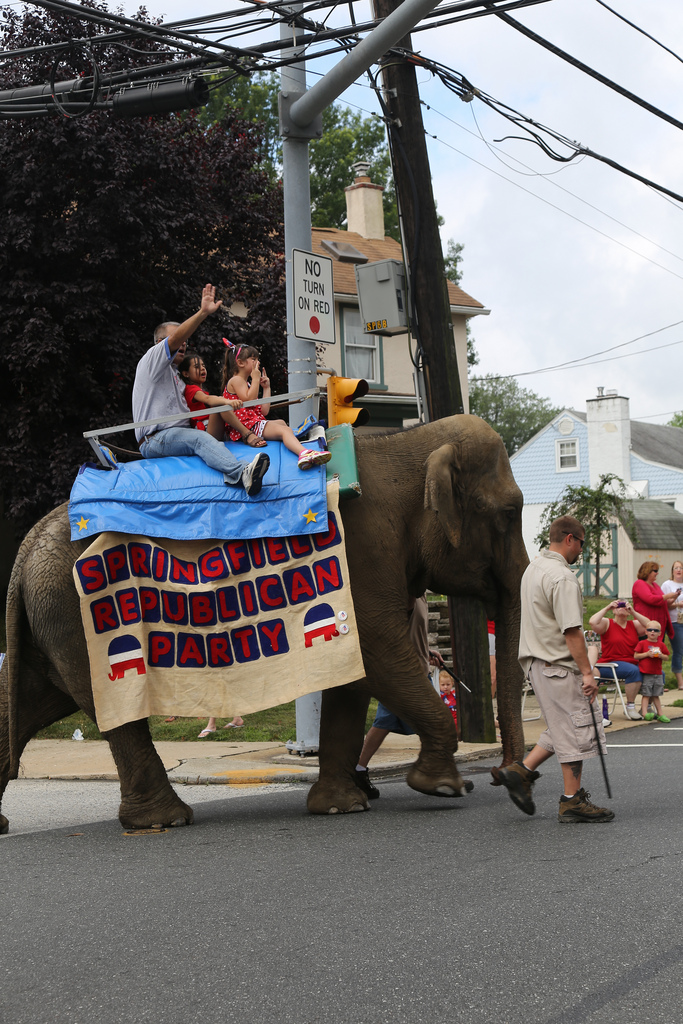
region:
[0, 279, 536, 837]
People riding an elephant on a street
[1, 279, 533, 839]
Three people riding an elephant down a street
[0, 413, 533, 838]
An elephant with a sign draped across their back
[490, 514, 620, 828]
A trainer walks beside an elephant carrying people on a street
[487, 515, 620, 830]
A trainer walks beside an elephant in a parade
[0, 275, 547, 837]
family riding an elephant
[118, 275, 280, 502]
a man waving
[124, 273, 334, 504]
a man and his daughters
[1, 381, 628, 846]
elephant led by trainer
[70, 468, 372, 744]
blanket reading "Springfield Republican Party"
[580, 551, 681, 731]
spectators on a sidewalk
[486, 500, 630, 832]
man wearing cargo shorts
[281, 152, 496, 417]
beige house with a reddish roof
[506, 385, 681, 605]
shed in front of blue house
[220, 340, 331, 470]
the girl is young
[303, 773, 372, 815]
foot of an elephant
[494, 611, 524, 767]
trunk of an elephant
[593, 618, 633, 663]
the shirt is red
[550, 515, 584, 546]
the hair is brown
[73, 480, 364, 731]
banner on the elephant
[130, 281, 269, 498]
the man is waving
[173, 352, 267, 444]
girl on the elephant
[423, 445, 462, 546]
ear of an elephant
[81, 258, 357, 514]
people on the elephant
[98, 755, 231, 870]
back foot of the elephant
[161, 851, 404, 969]
street next to the elephant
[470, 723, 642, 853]
shoes on the person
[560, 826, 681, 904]
crack on the street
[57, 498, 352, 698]
writing on the item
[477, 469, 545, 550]
eye of the elephant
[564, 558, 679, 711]
people wearing red clothing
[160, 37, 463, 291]
A tree in a city.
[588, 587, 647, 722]
A person is sitting down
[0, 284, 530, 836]
the people on the elephant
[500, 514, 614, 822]
the man is walking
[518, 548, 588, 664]
the shirt is beige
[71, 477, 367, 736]
the letters are red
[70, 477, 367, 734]
the letters on the cloth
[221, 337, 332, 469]
the girl is sitting down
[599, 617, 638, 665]
the shirt is red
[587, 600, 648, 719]
the woman wearing a red shirt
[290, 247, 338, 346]
White and black rectangle sign with red circle on it.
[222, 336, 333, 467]
Brown haired girl on the front of an elephant with her fingers up.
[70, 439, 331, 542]
Blue blanket on the elephant top.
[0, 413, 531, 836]
Large brown elephant with people on top.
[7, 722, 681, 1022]
A dark grey paved road.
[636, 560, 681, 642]
Brown haired woman in black sunglasses and pink top.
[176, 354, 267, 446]
Girl on the elephant in red.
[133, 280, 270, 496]
Grey haired man with his hand up on the elephant.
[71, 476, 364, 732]
Banner on the elephant that reads: SPRINGFIELD REPUBLICAN PARTY.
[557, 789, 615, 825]
A mans brown and black right shoe.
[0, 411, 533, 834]
large grey tall elephant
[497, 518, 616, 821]
short white man with blonde hair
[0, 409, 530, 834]
full grown asian elephant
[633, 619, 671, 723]
young boy with sunglasses and green shoes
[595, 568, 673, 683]
three people in red shirts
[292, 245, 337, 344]
traffic sign with a red dot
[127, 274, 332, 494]
three people riding on an elephant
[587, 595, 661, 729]
lady sitting on a lawn chair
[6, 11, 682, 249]
heavy utility lines above